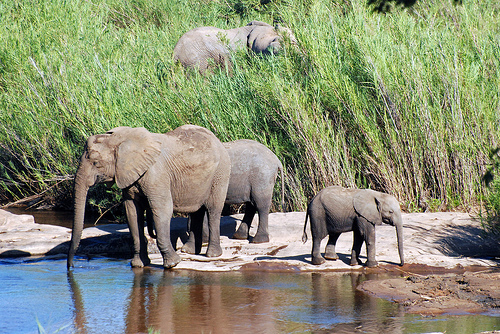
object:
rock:
[3, 201, 38, 229]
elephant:
[220, 138, 286, 242]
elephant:
[171, 20, 296, 77]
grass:
[0, 0, 500, 212]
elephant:
[301, 186, 403, 268]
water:
[0, 251, 499, 334]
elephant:
[67, 124, 231, 271]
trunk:
[65, 167, 100, 272]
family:
[69, 22, 406, 268]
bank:
[0, 195, 499, 318]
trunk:
[392, 218, 404, 267]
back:
[250, 166, 273, 229]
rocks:
[352, 266, 499, 314]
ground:
[0, 200, 500, 334]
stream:
[1, 252, 500, 334]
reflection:
[122, 271, 276, 334]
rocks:
[0, 224, 75, 249]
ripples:
[6, 262, 272, 333]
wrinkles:
[155, 137, 196, 188]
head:
[66, 125, 162, 267]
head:
[243, 20, 299, 54]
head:
[352, 189, 404, 267]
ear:
[352, 190, 385, 225]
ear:
[247, 26, 273, 52]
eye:
[91, 159, 100, 167]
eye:
[387, 210, 393, 215]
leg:
[356, 217, 376, 258]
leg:
[138, 178, 174, 249]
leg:
[122, 195, 145, 242]